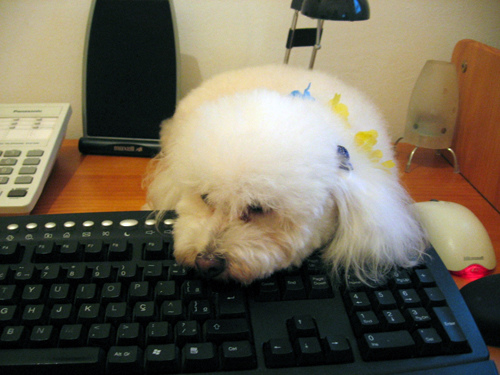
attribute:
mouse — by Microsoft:
[413, 193, 498, 279]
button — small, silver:
[6, 222, 18, 232]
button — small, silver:
[23, 219, 39, 230]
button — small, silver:
[41, 219, 56, 229]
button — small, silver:
[61, 217, 74, 229]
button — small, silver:
[80, 217, 92, 228]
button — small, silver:
[98, 216, 113, 228]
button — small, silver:
[118, 215, 137, 227]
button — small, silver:
[142, 217, 158, 226]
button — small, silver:
[158, 213, 173, 223]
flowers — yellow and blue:
[278, 68, 422, 194]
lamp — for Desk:
[271, 1, 346, 76]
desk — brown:
[3, 7, 499, 369]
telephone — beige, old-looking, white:
[3, 97, 80, 222]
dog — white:
[174, 63, 415, 277]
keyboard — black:
[7, 193, 492, 368]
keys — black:
[34, 249, 274, 349]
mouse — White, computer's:
[385, 169, 498, 281]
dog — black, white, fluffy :
[141, 61, 439, 286]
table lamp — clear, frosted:
[416, 56, 459, 156]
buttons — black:
[60, 273, 233, 340]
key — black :
[129, 279, 146, 297]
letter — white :
[134, 283, 143, 290]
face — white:
[173, 116, 326, 283]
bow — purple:
[319, 140, 376, 175]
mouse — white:
[400, 188, 497, 275]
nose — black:
[175, 214, 237, 275]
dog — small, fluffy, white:
[145, 66, 428, 279]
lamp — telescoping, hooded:
[273, 0, 375, 67]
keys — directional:
[271, 307, 341, 364]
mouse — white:
[410, 199, 495, 269]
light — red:
[463, 265, 490, 278]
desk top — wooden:
[5, 114, 425, 211]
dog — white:
[72, 36, 444, 333]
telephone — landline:
[0, 86, 98, 235]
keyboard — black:
[33, 195, 473, 365]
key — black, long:
[201, 313, 256, 338]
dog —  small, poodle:
[64, 24, 451, 310]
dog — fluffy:
[126, 81, 410, 258]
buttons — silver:
[5, 237, 462, 367]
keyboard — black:
[0, 203, 498, 372]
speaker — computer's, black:
[79, 0, 177, 167]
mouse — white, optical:
[408, 197, 496, 277]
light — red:
[465, 263, 485, 274]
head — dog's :
[145, 89, 422, 282]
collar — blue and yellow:
[275, 86, 397, 167]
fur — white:
[152, 51, 439, 298]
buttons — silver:
[2, 211, 167, 260]